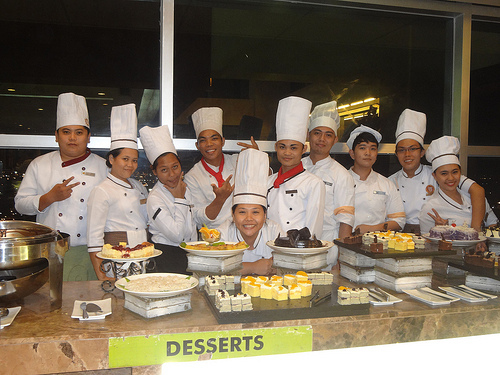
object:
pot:
[0, 222, 76, 314]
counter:
[0, 280, 499, 375]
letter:
[165, 342, 180, 355]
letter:
[184, 340, 192, 355]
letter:
[193, 339, 204, 353]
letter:
[206, 337, 216, 353]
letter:
[219, 338, 229, 352]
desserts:
[275, 227, 327, 248]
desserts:
[428, 223, 482, 240]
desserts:
[359, 232, 429, 251]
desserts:
[123, 276, 190, 291]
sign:
[105, 324, 315, 369]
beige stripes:
[386, 210, 408, 221]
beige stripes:
[333, 201, 357, 216]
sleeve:
[383, 183, 410, 225]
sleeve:
[332, 170, 359, 226]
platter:
[70, 295, 116, 321]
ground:
[311, 88, 336, 129]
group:
[14, 91, 498, 283]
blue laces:
[235, 264, 312, 309]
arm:
[11, 151, 54, 214]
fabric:
[270, 160, 306, 188]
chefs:
[183, 102, 235, 237]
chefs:
[264, 92, 325, 235]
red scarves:
[272, 164, 307, 181]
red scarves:
[194, 157, 232, 185]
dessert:
[336, 284, 351, 305]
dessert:
[348, 286, 359, 304]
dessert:
[358, 284, 370, 304]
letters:
[164, 335, 264, 357]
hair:
[358, 138, 370, 142]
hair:
[107, 152, 114, 158]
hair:
[155, 154, 165, 157]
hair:
[80, 126, 90, 133]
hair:
[230, 204, 237, 213]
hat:
[347, 126, 381, 145]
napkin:
[72, 297, 112, 321]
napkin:
[362, 282, 401, 307]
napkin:
[401, 285, 462, 310]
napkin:
[438, 280, 498, 306]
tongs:
[306, 285, 333, 312]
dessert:
[270, 285, 290, 300]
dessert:
[239, 290, 254, 305]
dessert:
[146, 240, 154, 254]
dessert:
[370, 242, 382, 253]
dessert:
[359, 230, 376, 247]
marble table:
[0, 279, 500, 375]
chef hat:
[53, 93, 88, 128]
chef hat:
[106, 101, 139, 151]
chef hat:
[137, 125, 180, 166]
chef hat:
[188, 105, 222, 138]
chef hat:
[230, 147, 270, 207]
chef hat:
[274, 95, 309, 149]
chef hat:
[311, 101, 338, 138]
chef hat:
[425, 132, 460, 174]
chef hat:
[394, 105, 426, 147]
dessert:
[180, 228, 249, 277]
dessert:
[330, 223, 458, 293]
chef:
[205, 145, 291, 280]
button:
[75, 196, 86, 203]